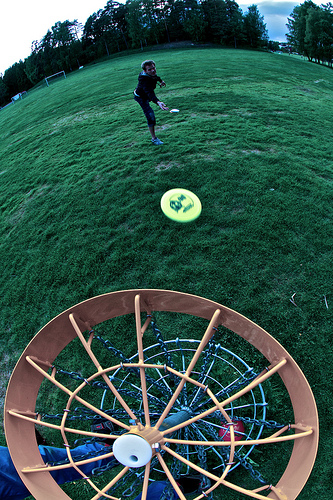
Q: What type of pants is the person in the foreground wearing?
A: Jeans.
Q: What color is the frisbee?
A: Yellow.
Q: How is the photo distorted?
A: It bends down on both sides.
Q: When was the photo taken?
A: During the day.